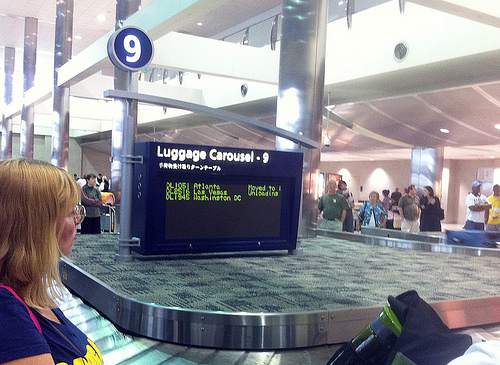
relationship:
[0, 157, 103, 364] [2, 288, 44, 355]
woman has shoulder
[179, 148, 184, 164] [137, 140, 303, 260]
white letter on sign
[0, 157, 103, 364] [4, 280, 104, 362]
woman wearing shirt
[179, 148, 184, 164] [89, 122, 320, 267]
white letter on sign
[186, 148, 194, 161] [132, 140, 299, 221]
letter on sign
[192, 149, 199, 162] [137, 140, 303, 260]
letter on sign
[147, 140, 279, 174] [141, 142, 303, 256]
white letter on sign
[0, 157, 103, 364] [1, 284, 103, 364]
woman wearing shirt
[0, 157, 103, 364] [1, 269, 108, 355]
woman wearing shirt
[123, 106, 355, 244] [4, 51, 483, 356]
sign shows terminal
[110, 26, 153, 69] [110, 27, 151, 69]
nine in circle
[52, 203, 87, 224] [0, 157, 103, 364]
glasses on woman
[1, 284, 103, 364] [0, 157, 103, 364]
shirt of woman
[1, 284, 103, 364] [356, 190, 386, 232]
shirt of woman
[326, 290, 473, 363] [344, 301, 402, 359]
backpack with cup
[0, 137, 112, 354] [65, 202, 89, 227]
woman wearing glasses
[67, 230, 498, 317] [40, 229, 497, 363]
area in middle of luggage carousel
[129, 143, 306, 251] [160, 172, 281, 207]
electronic display of information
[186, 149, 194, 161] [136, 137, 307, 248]
letter on sign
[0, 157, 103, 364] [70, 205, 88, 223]
woman with glasses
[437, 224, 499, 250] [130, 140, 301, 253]
luggage for status board